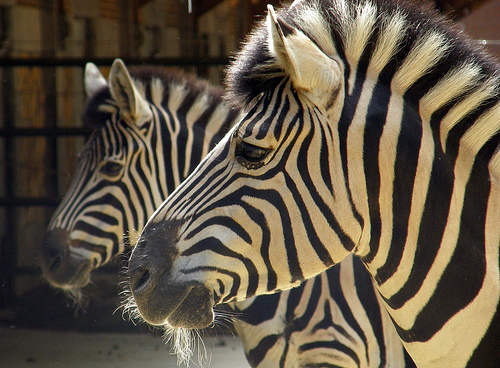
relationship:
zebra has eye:
[129, 0, 499, 366] [236, 142, 269, 161]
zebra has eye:
[40, 56, 416, 368] [102, 160, 122, 173]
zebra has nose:
[129, 0, 499, 366] [128, 220, 181, 320]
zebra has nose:
[40, 56, 416, 368] [40, 229, 72, 287]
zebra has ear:
[129, 0, 499, 366] [263, 1, 341, 109]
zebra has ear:
[40, 56, 416, 368] [83, 60, 107, 101]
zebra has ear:
[40, 56, 416, 368] [108, 57, 150, 125]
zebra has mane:
[129, 0, 499, 366] [223, 0, 499, 178]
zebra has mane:
[40, 56, 416, 368] [79, 63, 245, 132]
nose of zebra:
[128, 220, 181, 320] [129, 0, 499, 366]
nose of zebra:
[40, 229, 72, 287] [40, 56, 416, 368]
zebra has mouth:
[129, 0, 499, 366] [148, 277, 217, 332]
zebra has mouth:
[40, 56, 416, 368] [59, 258, 94, 293]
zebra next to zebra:
[129, 0, 499, 366] [40, 56, 416, 368]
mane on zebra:
[223, 0, 499, 178] [129, 0, 499, 366]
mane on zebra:
[79, 63, 245, 132] [40, 56, 416, 368]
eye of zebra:
[236, 142, 269, 161] [129, 0, 499, 366]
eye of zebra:
[102, 160, 122, 173] [40, 56, 416, 368]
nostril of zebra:
[132, 262, 153, 292] [129, 0, 499, 366]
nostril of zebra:
[47, 254, 63, 273] [40, 56, 416, 368]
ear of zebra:
[263, 1, 341, 109] [129, 0, 499, 366]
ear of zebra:
[83, 60, 107, 101] [40, 56, 416, 368]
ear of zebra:
[108, 57, 150, 125] [40, 56, 416, 368]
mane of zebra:
[223, 0, 499, 178] [129, 0, 499, 366]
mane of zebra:
[79, 63, 245, 132] [40, 56, 416, 368]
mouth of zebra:
[148, 277, 217, 332] [129, 0, 499, 366]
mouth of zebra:
[59, 258, 94, 293] [40, 56, 416, 368]